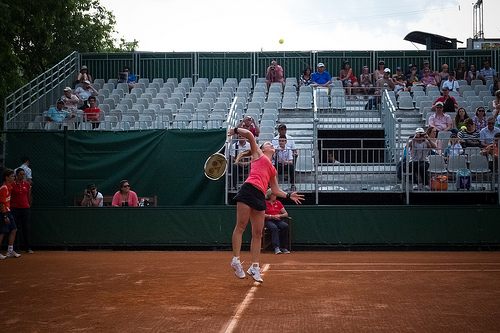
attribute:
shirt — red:
[21, 177, 33, 209]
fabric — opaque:
[88, 45, 488, 82]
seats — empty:
[113, 82, 300, 106]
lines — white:
[220, 260, 497, 331]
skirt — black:
[236, 180, 268, 217]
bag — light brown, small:
[429, 172, 448, 189]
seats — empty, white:
[143, 78, 229, 127]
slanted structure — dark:
[404, 28, 461, 52]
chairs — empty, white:
[121, 74, 275, 121]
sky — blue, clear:
[0, 0, 498, 55]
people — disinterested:
[428, 99, 455, 142]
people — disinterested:
[405, 124, 430, 182]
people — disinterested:
[470, 102, 487, 132]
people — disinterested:
[483, 130, 497, 170]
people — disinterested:
[453, 104, 472, 127]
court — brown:
[44, 240, 247, 332]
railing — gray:
[228, 140, 495, 204]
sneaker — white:
[231, 261, 247, 282]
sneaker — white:
[248, 265, 263, 277]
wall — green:
[4, 131, 225, 213]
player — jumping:
[224, 122, 307, 286]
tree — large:
[16, 16, 121, 66]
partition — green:
[18, 206, 482, 260]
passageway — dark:
[316, 122, 386, 172]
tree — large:
[2, 4, 125, 70]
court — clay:
[19, 239, 484, 331]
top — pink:
[238, 147, 285, 191]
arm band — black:
[231, 124, 240, 137]